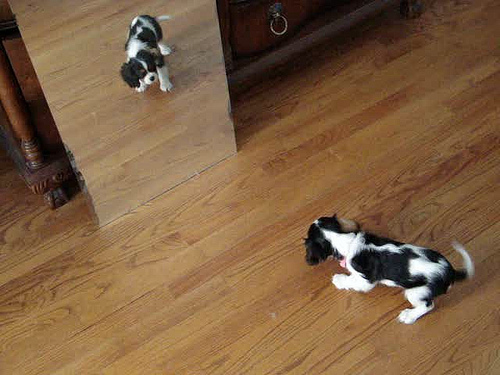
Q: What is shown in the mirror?
A: Reflection of puppy.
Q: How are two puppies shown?
A: One is reflected by a mirror.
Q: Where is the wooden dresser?
A: Behind the mirror.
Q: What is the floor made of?
A: Wood.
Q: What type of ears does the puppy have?
A: Floppy.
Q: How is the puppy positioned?
A: On all fours.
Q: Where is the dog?
A: On the ground.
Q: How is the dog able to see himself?
A: The mirror.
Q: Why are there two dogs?
A: Reflection of dog in mirror.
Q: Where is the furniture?
A: Behind the mirror.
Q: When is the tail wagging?
A: Now.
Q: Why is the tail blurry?
A: It is wagging.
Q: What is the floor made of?
A: Wood.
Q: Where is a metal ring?
A: On the furniture.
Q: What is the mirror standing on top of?
A: Floor.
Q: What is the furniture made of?
A: Wood.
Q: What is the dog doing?
A: Looking in the mirror.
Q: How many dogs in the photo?
A: One.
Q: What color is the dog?
A: Black and white.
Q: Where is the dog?
A: The floor.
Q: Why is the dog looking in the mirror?
A: To see himself.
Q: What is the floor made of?
A: Wood.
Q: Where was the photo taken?
A: In a bedroom.